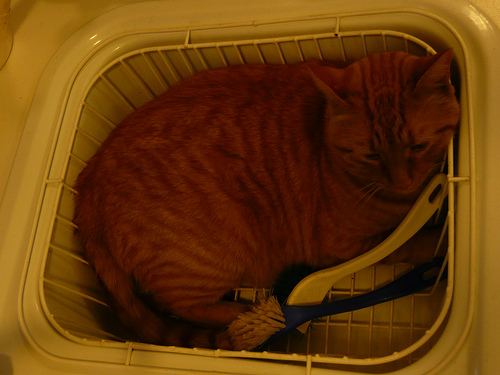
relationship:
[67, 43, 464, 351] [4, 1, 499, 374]
cat in sink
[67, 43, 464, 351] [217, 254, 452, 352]
cat with scrub brush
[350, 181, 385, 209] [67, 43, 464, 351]
whisker of cat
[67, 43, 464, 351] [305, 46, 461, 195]
cat has head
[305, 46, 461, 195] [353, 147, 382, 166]
head has eye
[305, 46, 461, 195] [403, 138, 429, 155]
head has eye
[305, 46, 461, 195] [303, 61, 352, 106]
head has ear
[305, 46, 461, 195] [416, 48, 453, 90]
head has ear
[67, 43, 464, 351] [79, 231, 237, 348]
cat has tail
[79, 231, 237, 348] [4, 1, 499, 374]
tail in sink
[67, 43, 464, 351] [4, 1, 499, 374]
cat lying in sink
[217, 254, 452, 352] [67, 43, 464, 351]
scrub brush near cat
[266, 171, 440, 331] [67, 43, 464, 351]
scrub brush near cat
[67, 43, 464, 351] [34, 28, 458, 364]
cat in wire basket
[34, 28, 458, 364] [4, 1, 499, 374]
wire basket in sink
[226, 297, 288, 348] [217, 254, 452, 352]
bristles on scrub brush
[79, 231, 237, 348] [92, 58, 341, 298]
tail curled around body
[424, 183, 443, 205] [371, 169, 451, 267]
opening on handle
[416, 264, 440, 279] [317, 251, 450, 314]
opening on handle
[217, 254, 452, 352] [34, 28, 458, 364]
scrub brush in wire basket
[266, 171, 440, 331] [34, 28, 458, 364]
scrub brush in wire basket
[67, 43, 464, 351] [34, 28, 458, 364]
cat lying in wire basket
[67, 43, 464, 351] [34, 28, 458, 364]
cat curled up in wire basket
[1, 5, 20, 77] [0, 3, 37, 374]
jar on shelf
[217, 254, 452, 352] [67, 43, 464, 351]
scrub brush next to cat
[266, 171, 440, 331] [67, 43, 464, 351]
scrub brush next to cat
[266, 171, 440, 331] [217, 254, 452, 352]
scrub brush next to scrub brush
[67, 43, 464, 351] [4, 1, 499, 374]
cat sitting in sink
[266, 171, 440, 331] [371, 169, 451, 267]
scrub brush has handle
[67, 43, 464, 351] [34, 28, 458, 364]
cat sitting in wire basket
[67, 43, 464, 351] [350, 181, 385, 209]
cat has whisker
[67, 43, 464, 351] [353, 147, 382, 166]
cat has eye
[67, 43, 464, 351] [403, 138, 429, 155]
cat has eye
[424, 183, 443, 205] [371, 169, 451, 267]
opening in handle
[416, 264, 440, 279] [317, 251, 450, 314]
opening in handle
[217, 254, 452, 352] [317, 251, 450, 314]
scrub brush has handle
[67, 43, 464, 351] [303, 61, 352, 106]
cat has ear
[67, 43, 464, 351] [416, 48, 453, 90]
cat has ear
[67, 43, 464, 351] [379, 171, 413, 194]
cat has nose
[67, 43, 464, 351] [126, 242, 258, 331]
cat has hind leg